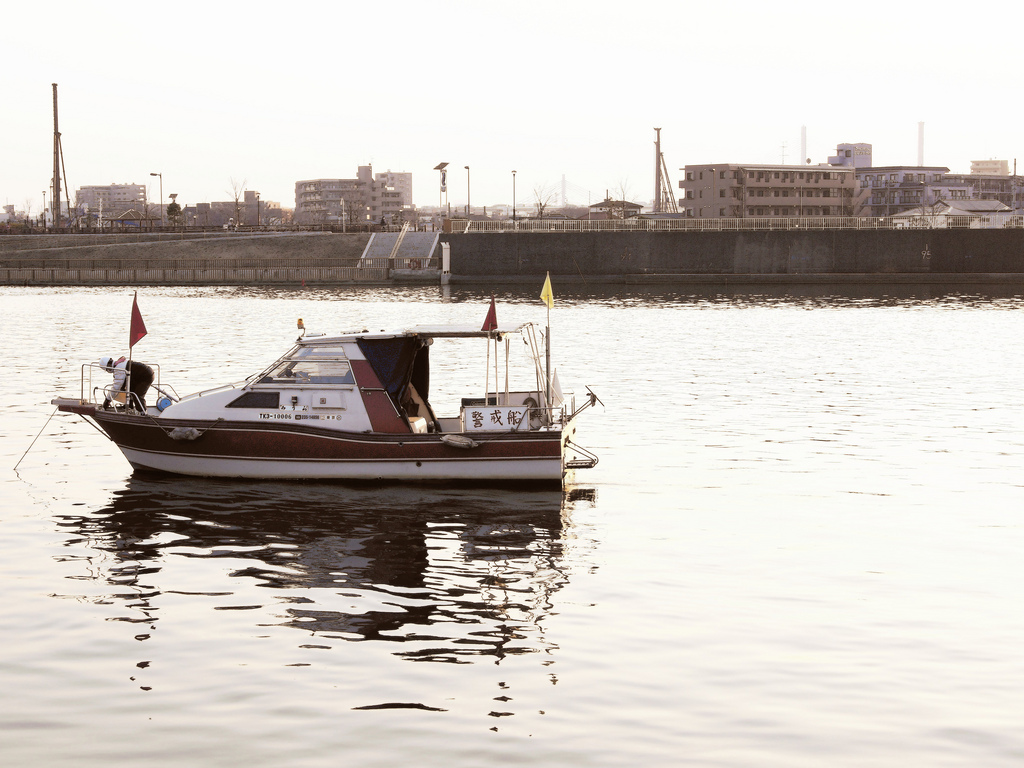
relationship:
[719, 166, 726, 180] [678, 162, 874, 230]
window on a building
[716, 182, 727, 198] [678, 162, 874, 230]
window on a building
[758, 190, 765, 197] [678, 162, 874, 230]
window on a building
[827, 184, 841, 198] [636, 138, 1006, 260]
window on a building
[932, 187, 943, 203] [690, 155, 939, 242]
window on a building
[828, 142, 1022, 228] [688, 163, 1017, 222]
building in a city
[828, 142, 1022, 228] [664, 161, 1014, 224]
building in a city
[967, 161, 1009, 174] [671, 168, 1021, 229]
building in a city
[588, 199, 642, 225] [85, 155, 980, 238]
building in a city